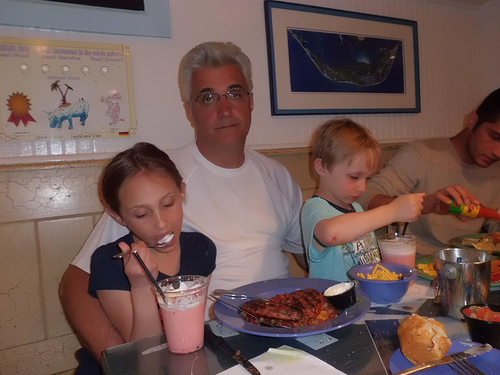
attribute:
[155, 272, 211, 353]
milkshake — one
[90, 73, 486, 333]
people — some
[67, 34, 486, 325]
people — some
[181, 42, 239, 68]
hair — grey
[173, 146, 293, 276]
shirt — white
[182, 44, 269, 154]
man — one